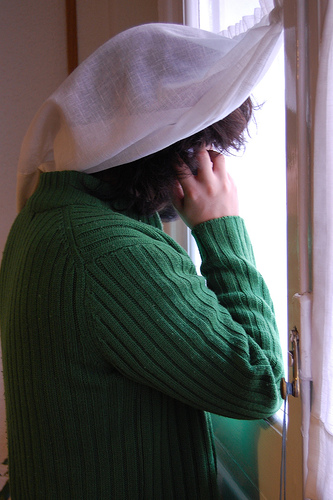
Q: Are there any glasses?
A: No, there are no glasses.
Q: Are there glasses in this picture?
A: No, there are no glasses.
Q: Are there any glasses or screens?
A: No, there are no glasses or screens.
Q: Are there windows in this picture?
A: Yes, there is a window.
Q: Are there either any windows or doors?
A: Yes, there is a window.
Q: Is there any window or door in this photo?
A: Yes, there is a window.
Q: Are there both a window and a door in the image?
A: Yes, there are both a window and a door.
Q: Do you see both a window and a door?
A: Yes, there are both a window and a door.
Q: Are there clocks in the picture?
A: No, there are no clocks.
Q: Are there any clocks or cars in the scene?
A: No, there are no clocks or cars.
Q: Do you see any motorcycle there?
A: No, there are no motorcycles.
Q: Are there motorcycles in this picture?
A: No, there are no motorcycles.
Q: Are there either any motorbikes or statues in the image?
A: No, there are no motorbikes or statues.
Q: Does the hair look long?
A: Yes, the hair is long.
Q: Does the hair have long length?
A: Yes, the hair is long.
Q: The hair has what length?
A: The hair is long.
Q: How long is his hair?
A: The hair is long.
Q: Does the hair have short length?
A: No, the hair is long.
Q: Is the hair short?
A: No, the hair is long.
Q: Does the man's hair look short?
A: No, the hair is long.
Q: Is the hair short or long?
A: The hair is long.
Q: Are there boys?
A: No, there are no boys.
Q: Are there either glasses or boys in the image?
A: No, there are no boys or glasses.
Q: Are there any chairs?
A: No, there are no chairs.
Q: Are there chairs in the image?
A: No, there are no chairs.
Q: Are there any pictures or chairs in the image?
A: No, there are no chairs or pictures.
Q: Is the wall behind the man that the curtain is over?
A: Yes, the wall is behind the man.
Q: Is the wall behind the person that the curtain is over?
A: Yes, the wall is behind the man.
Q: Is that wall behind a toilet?
A: No, the wall is behind the man.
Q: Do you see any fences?
A: No, there are no fences.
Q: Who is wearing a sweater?
A: The man is wearing a sweater.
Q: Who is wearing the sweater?
A: The man is wearing a sweater.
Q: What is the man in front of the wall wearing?
A: The man is wearing a sweater.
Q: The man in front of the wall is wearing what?
A: The man is wearing a sweater.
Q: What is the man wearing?
A: The man is wearing a sweater.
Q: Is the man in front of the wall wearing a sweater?
A: Yes, the man is wearing a sweater.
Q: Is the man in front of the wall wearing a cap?
A: No, the man is wearing a sweater.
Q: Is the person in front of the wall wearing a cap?
A: No, the man is wearing a sweater.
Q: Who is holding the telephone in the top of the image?
A: The man is holding the phone.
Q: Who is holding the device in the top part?
A: The man is holding the phone.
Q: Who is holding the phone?
A: The man is holding the phone.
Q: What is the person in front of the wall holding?
A: The man is holding the telephone.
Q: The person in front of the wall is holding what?
A: The man is holding the telephone.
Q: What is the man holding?
A: The man is holding the telephone.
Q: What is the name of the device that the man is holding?
A: The device is a phone.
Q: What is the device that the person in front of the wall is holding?
A: The device is a phone.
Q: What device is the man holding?
A: The man is holding the telephone.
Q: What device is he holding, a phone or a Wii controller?
A: The man is holding a phone.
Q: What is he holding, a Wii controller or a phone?
A: The man is holding a phone.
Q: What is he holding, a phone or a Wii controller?
A: The man is holding a phone.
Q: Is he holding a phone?
A: Yes, the man is holding a phone.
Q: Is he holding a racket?
A: No, the man is holding a phone.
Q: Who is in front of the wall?
A: The man is in front of the wall.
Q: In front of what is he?
A: The man is in front of the wall.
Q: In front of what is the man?
A: The man is in front of the wall.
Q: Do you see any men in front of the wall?
A: Yes, there is a man in front of the wall.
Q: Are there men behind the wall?
A: No, the man is in front of the wall.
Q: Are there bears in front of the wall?
A: No, there is a man in front of the wall.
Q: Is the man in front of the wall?
A: Yes, the man is in front of the wall.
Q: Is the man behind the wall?
A: No, the man is in front of the wall.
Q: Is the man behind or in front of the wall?
A: The man is in front of the wall.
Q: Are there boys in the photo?
A: No, there are no boys.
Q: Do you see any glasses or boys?
A: No, there are no boys or glasses.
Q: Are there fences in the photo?
A: No, there are no fences.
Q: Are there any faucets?
A: No, there are no faucets.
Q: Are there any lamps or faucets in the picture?
A: No, there are no faucets or lamps.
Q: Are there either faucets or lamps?
A: No, there are no faucets or lamps.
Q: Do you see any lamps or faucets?
A: No, there are no faucets or lamps.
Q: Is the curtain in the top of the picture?
A: Yes, the curtain is in the top of the image.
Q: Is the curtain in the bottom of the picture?
A: No, the curtain is in the top of the image.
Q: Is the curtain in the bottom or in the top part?
A: The curtain is in the top of the image.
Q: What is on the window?
A: The curtain is on the window.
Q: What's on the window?
A: The curtain is on the window.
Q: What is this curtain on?
A: The curtain is on the window.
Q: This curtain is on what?
A: The curtain is on the window.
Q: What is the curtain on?
A: The curtain is on the window.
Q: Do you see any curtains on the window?
A: Yes, there is a curtain on the window.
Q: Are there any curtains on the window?
A: Yes, there is a curtain on the window.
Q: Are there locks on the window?
A: No, there is a curtain on the window.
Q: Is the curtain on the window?
A: Yes, the curtain is on the window.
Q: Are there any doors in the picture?
A: Yes, there is a door.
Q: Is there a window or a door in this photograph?
A: Yes, there is a door.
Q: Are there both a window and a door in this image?
A: Yes, there are both a door and a window.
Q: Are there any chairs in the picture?
A: No, there are no chairs.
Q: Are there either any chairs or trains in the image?
A: No, there are no chairs or trains.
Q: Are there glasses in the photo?
A: No, there are no glasses.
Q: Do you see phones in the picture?
A: Yes, there is a phone.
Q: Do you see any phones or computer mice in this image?
A: Yes, there is a phone.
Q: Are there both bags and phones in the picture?
A: No, there is a phone but no bags.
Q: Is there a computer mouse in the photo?
A: No, there are no computer mice.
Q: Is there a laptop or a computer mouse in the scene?
A: No, there are no computer mice or laptops.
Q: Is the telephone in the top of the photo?
A: Yes, the telephone is in the top of the image.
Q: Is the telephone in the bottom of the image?
A: No, the telephone is in the top of the image.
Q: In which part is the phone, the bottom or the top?
A: The phone is in the top of the image.